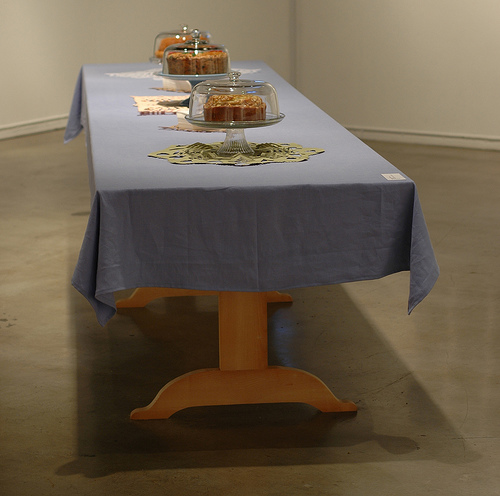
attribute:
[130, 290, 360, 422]
leg — wood, wooden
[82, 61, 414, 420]
table — wooden, brown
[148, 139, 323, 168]
doily — green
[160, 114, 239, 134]
mat — brown, tan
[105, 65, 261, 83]
doily — white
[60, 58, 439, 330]
tablecloth — blue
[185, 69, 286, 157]
cake dish — glass, clear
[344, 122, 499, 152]
baseboard — white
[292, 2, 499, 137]
wall — white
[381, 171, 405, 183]
card — white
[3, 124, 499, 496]
floor — gray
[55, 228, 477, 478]
shadow — black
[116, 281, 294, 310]
leg — wooden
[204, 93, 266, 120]
cake — brown, light brown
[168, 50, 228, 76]
cake — brown, light brown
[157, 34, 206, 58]
cake — brown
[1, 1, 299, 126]
wall — white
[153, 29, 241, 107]
cake dish — glass